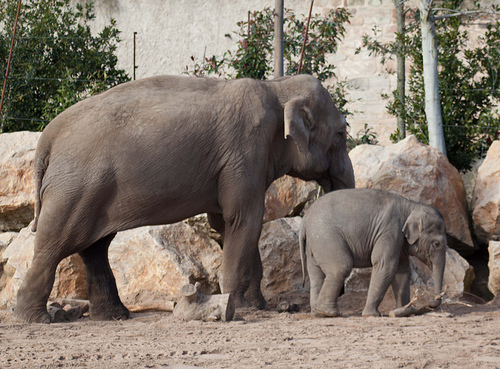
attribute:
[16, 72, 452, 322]
elephants — walking, in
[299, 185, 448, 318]
elephant — baby, wrinkled, small, taskless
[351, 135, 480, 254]
rock — large, tan, brown, big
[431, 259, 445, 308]
trunk — gray, larger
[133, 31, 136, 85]
pole — narrow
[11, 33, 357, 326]
elephant — large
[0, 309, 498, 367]
dirt — brown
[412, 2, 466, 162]
tree — tall, in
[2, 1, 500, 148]
wall — brick, concrete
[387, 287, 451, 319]
branch — fallen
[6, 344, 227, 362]
marks — tire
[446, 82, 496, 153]
bush — green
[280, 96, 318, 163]
ears — floppy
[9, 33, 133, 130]
fence — electrical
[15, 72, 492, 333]
scene — outdoors